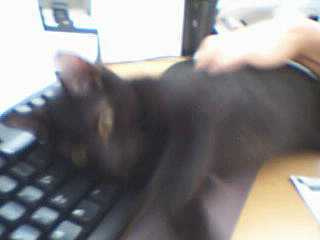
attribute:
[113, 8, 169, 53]
wall — white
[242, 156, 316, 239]
table — brown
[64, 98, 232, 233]
cat — blurry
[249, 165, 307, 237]
desk top — wooden 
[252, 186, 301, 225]
table — wooden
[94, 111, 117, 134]
eye — blurry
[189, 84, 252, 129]
fur — black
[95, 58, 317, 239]
table — wooden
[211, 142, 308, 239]
desktop — wooden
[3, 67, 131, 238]
keyboard — black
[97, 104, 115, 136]
eye — green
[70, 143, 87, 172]
eye — green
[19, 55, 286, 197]
cat — black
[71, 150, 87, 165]
eye — blurry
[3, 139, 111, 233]
keyboard — black 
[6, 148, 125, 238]
buttons — black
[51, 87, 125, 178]
eyes — yellow or green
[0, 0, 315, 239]
picture — blurry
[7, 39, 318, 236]
cat — black, big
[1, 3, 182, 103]
background — white